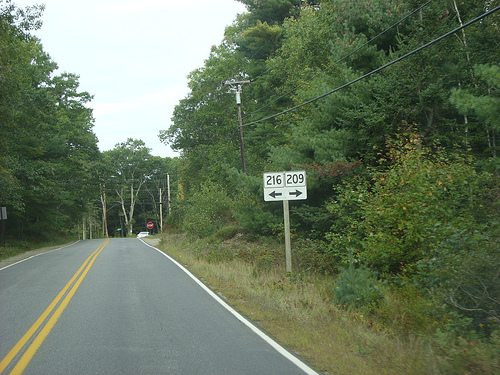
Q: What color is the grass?
A: Yellow and green.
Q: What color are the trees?
A: Green.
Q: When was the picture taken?
A: Daytime.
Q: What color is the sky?
A: Blue.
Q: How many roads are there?
A: One.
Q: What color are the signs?
A: Black and white.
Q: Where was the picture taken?
A: In the street.